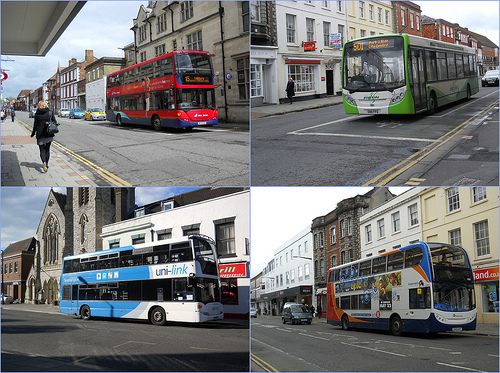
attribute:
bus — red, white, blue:
[323, 238, 480, 338]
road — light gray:
[18, 110, 248, 185]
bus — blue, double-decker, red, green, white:
[58, 233, 225, 327]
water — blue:
[227, 129, 248, 146]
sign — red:
[294, 40, 320, 54]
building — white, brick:
[252, 220, 317, 293]